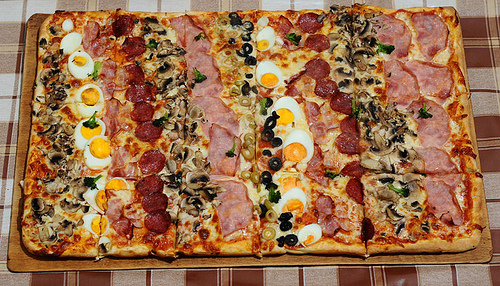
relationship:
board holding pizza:
[1, 8, 493, 275] [21, 8, 484, 260]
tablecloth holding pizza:
[2, 4, 496, 282] [21, 8, 484, 260]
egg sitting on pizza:
[270, 97, 303, 132] [21, 8, 484, 260]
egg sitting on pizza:
[282, 129, 312, 169] [21, 8, 484, 260]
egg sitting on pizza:
[280, 191, 306, 220] [21, 8, 484, 260]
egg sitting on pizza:
[290, 227, 320, 241] [21, 8, 484, 260]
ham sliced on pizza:
[209, 179, 251, 237] [21, 8, 484, 260]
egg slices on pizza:
[248, 11, 329, 243] [16, 27, 478, 252]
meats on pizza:
[108, 20, 173, 229] [48, 18, 453, 235]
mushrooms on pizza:
[32, 69, 112, 256] [21, 8, 484, 260]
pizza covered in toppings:
[21, 8, 484, 260] [30, 7, 460, 245]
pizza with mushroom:
[21, 8, 484, 260] [46, 65, 96, 235]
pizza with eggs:
[21, 8, 484, 260] [244, 35, 324, 240]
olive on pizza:
[253, 224, 280, 249] [16, 10, 493, 284]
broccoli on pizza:
[388, 179, 402, 194] [21, 8, 484, 260]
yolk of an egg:
[90, 139, 112, 159] [75, 131, 113, 171]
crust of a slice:
[363, 172, 480, 254] [361, 170, 483, 253]